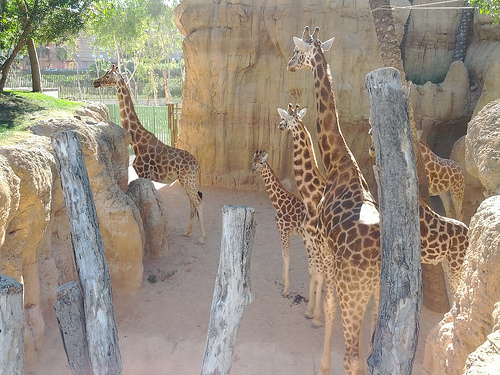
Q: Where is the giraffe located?
A: In stone enclosure.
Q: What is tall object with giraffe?
A: Wooden stick.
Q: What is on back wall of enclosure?
A: Rock wall.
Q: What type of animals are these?
A: Giraffes.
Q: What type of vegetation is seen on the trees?
A: Leaves.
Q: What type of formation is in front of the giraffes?
A: A large rock wall.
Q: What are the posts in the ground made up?
A: Wood.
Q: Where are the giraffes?
A: In an enclosure at the zoo.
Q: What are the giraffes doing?
A: Standing in a group.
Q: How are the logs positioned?
A: They're standing upright.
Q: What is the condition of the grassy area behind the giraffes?
A: Green and lush.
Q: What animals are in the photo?
A: Giraffes.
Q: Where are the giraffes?
A: Zoo.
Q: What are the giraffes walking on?
A: Dirt.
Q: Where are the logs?
A: In ground.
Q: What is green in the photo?
A: Tree leaves.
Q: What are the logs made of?
A: Wood.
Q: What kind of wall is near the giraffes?
A: Rock wall.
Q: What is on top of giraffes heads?
A: Horns.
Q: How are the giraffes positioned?
A: Standing.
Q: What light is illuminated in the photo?
A: Sunlight.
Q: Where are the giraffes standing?
A: In between rocks.